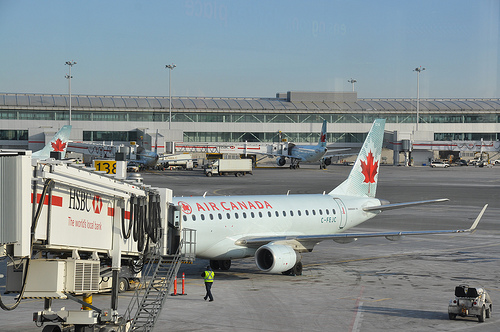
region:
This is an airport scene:
[9, 55, 487, 322]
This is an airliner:
[168, 120, 458, 285]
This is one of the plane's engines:
[250, 231, 310, 282]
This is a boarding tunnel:
[3, 145, 184, 270]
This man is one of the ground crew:
[195, 260, 220, 300]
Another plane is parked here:
[245, 120, 355, 170]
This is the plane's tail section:
[337, 115, 447, 220]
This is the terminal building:
[5, 85, 495, 146]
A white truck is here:
[200, 155, 256, 180]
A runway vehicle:
[445, 276, 497, 325]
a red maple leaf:
[326, 114, 418, 228]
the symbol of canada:
[313, 102, 457, 244]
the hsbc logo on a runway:
[33, 165, 146, 232]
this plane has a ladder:
[121, 194, 231, 322]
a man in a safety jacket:
[193, 257, 235, 328]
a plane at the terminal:
[8, 89, 468, 306]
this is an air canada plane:
[181, 189, 353, 241]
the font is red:
[186, 159, 305, 218]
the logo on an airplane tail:
[312, 126, 447, 257]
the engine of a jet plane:
[235, 236, 319, 286]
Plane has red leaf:
[344, 110, 402, 199]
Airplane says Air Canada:
[178, 194, 283, 214]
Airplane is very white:
[173, 177, 410, 271]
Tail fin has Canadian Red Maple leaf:
[346, 116, 393, 206]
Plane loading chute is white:
[4, 150, 174, 264]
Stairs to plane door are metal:
[120, 225, 197, 330]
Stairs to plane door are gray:
[128, 223, 195, 328]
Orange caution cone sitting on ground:
[168, 270, 178, 302]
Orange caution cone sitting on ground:
[180, 268, 186, 304]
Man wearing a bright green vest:
[199, 260, 231, 306]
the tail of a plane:
[325, 108, 400, 200]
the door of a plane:
[326, 192, 350, 228]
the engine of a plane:
[248, 231, 313, 276]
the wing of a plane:
[233, 199, 494, 254]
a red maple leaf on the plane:
[352, 145, 391, 195]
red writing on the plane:
[194, 194, 274, 217]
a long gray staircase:
[111, 247, 191, 330]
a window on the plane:
[198, 209, 209, 223]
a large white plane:
[163, 109, 491, 276]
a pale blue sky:
[0, 0, 498, 100]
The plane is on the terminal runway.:
[167, 181, 379, 264]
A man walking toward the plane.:
[189, 257, 224, 309]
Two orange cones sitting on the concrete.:
[167, 266, 190, 308]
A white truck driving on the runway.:
[191, 144, 266, 185]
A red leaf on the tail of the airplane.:
[358, 152, 399, 189]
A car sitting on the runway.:
[450, 261, 487, 311]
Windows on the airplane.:
[173, 193, 338, 225]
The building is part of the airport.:
[53, 96, 456, 171]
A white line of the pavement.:
[351, 273, 368, 330]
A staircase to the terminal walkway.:
[136, 244, 185, 330]